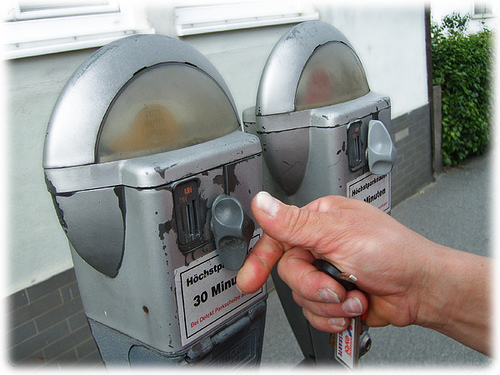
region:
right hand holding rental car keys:
[234, 187, 492, 364]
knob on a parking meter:
[204, 187, 256, 281]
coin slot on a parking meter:
[166, 174, 209, 259]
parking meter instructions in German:
[174, 257, 265, 339]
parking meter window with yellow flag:
[88, 61, 240, 161]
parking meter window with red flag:
[282, 37, 375, 111]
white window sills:
[12, 5, 325, 57]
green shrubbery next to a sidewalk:
[432, 13, 493, 178]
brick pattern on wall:
[10, 284, 94, 371]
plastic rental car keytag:
[333, 300, 357, 365]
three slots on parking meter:
[170, 199, 203, 241]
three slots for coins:
[162, 186, 212, 265]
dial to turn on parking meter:
[214, 172, 269, 255]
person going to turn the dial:
[202, 185, 303, 318]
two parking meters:
[119, 23, 412, 265]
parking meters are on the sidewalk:
[80, 15, 341, 106]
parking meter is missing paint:
[26, 118, 242, 242]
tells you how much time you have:
[130, 89, 188, 150]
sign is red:
[303, 63, 346, 120]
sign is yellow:
[95, 100, 194, 146]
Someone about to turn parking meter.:
[196, 177, 316, 291]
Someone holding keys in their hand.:
[235, 180, 480, 346]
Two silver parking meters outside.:
[43, 18, 435, 331]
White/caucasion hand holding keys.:
[235, 185, 480, 351]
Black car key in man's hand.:
[308, 255, 363, 295]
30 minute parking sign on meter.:
[175, 260, 263, 330]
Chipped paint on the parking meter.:
[38, 35, 245, 365]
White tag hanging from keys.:
[55, 28, 400, 356]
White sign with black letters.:
[46, 16, 407, 367]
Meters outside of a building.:
[45, 17, 421, 353]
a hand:
[258, 145, 341, 313]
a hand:
[278, 92, 383, 354]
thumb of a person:
[251, 185, 347, 254]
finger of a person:
[232, 229, 292, 299]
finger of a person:
[273, 241, 348, 311]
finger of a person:
[292, 284, 369, 322]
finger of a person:
[297, 300, 350, 337]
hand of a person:
[228, 176, 425, 346]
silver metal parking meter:
[44, 19, 276, 374]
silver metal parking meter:
[234, 16, 411, 373]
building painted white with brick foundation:
[0, 6, 442, 373]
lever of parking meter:
[205, 191, 271, 276]